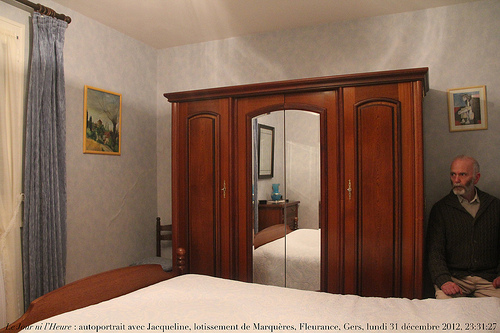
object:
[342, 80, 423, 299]
door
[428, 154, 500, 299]
man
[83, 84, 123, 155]
frame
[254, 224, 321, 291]
bed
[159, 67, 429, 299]
cupboard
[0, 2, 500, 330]
bedroom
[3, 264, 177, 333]
foot board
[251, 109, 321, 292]
mirror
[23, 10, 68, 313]
curtain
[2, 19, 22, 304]
window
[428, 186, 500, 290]
sweater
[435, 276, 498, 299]
pants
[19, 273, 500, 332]
bedspread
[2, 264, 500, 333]
bed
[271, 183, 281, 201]
vase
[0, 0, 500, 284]
wall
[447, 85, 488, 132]
picture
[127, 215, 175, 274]
chair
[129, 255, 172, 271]
cushion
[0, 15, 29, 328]
curtains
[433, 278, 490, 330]
chair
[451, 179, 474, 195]
facial hair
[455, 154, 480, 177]
hair line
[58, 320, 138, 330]
letter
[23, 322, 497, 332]
letter